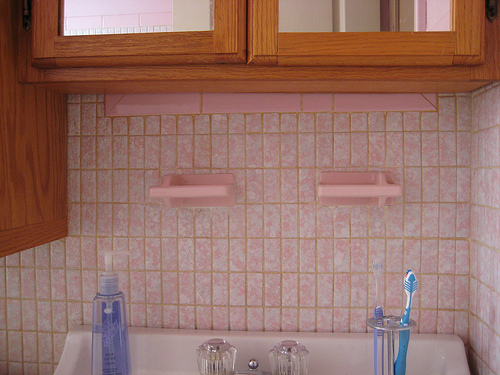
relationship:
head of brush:
[405, 268, 429, 288] [391, 257, 454, 329]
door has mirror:
[332, 4, 403, 49] [284, 11, 448, 39]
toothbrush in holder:
[394, 268, 426, 314] [364, 309, 414, 370]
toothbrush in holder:
[364, 252, 390, 372] [364, 309, 414, 370]